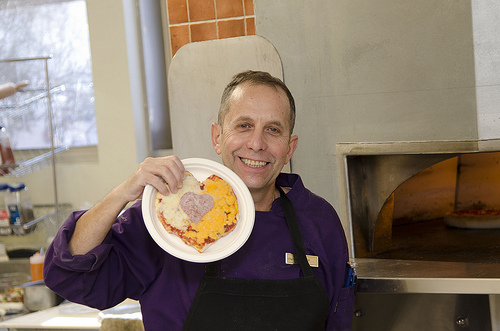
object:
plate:
[140, 157, 255, 264]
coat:
[41, 172, 357, 330]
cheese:
[208, 212, 238, 232]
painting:
[369, 151, 500, 262]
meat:
[180, 191, 214, 224]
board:
[167, 32, 289, 169]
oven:
[332, 138, 499, 331]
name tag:
[285, 252, 319, 267]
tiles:
[168, 18, 261, 57]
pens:
[351, 268, 356, 287]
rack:
[0, 53, 70, 229]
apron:
[183, 185, 335, 331]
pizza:
[153, 171, 239, 252]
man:
[41, 70, 357, 323]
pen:
[346, 265, 353, 287]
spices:
[7, 182, 36, 237]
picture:
[370, 122, 498, 262]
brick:
[161, 0, 253, 35]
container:
[7, 181, 36, 237]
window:
[0, 0, 101, 150]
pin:
[0, 80, 31, 100]